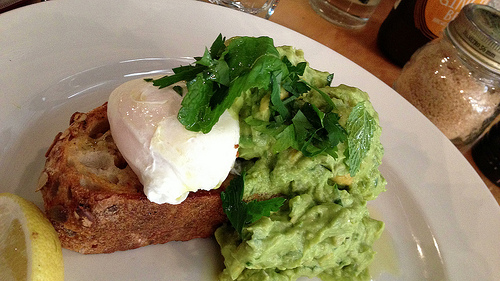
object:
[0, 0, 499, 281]
plate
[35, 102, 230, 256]
bread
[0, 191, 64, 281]
lemon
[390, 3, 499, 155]
jar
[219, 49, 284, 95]
leaves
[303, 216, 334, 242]
guacamole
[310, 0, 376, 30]
glass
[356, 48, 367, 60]
table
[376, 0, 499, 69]
bottle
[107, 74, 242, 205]
butter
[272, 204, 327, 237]
meat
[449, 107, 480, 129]
spices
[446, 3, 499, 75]
lid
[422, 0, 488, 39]
sticker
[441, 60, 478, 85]
cheese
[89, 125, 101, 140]
oats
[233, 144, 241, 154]
crumb